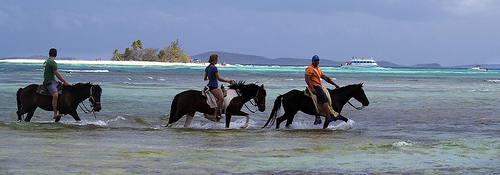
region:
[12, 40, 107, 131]
man looks back while riding a horse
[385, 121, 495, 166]
water near the shore line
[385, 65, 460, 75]
area of very blue water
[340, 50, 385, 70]
party boat out in the ocean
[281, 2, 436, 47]
partially cloudy sky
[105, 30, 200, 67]
small area of trees and beach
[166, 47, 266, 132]
woman riding a horse in the surf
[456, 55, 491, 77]
small boat on the waves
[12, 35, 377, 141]
three riding horses in the shallow water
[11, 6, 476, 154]
tourists enjoying an island paradise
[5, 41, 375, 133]
3 people on horses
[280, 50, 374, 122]
man in orange shirt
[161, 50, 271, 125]
woman in blue shirt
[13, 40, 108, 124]
man in green shirt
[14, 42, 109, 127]
left horse a little behind the other horses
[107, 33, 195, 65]
yellowish green bush in background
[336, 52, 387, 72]
white boat in background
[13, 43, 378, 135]
horses walking in water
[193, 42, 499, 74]
view of mountains behind water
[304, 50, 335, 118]
man in blue baseball cap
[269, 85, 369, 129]
a black horse in water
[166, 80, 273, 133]
a black horse in water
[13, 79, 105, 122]
a black horse in water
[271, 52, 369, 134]
a man riding a horse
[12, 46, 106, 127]
a man riding a horse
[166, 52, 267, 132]
a woman riding a horse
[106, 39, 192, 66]
a small distance island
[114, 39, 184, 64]
a range of trees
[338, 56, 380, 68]
a cruise ship in distancd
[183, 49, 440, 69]
land in distance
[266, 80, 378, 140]
The horse is walking in water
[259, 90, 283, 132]
The horses tail is black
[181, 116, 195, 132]
this part of the horses leg is white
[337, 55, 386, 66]
a white boat in the back ground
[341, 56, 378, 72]
The cruise boat is white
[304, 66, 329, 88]
the man is wearing an orange tee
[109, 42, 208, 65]
an island of trees in the water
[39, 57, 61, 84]
the man is wearing a green tee shirt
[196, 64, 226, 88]
the woman is wearing a blue tee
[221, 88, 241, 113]
this part of the horse is white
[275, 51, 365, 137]
man riding a horse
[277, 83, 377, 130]
horse walking in water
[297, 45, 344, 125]
man wearing a orange shirt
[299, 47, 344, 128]
man wearing a blue cap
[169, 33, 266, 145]
woman wearing a blue shirt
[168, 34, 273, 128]
woman riding a horse in the water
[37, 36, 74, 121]
man wearing a green shirt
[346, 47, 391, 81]
large white boat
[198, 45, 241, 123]
woman wearing short shorts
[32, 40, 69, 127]
man wearing sandals